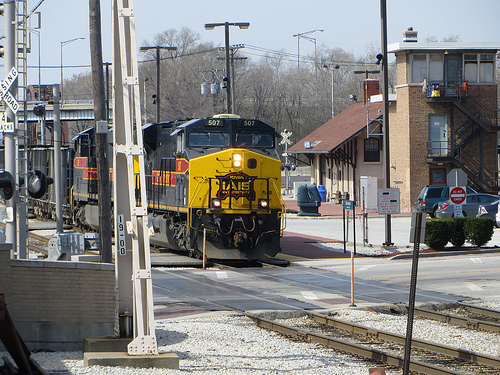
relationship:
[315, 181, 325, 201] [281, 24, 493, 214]
container in front of building